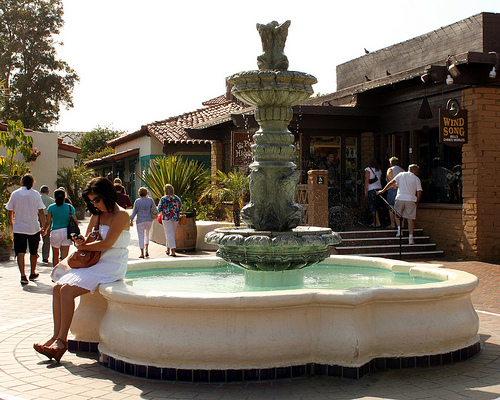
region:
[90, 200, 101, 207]
WOMAN IS WEARING SUN GLASSES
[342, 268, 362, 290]
WATER IN THE POND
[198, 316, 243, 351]
POND IS WHITE ON THE OUTSIDE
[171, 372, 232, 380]
LAYERS OF BRICKS AROUND THE BOTTOM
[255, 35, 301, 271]
WATER FOUNTAIN IN THE MIDDLE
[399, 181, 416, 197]
MAN IS WEARING A WHITE SHIRT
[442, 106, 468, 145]
SIGN ON THE SIDE OF WALL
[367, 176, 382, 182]
PURSE ON THE LADY ARM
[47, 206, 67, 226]
WOMAN WEARING A GREEN SHIRT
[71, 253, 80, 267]
LADY HOLDING PURSE IN ARMS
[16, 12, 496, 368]
A person is sitting on the water fountain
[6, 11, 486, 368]
People are walking around the area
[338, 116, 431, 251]
People are going into a building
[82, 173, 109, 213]
A person has dark colored hair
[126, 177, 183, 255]
Two people are walking somewhere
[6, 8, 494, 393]
The people are in a business area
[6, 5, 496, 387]
The people are out in the sunshine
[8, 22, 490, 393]
The people are on a vacation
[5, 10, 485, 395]
The people are enjoying their day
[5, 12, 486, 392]
The people are going to shop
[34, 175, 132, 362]
Woman sitting by fountain checking her cell phone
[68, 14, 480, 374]
Water fountain in the plaza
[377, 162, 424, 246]
Man wallking up steps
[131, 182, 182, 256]
Two women walking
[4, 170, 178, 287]
People waking in the stret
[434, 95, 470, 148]
Sign hanging from building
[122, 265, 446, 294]
Water in the fountain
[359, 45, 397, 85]
Three birds on the top of the building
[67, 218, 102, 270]
Brown purse in girl's arms.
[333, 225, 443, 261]
Steps to building entrance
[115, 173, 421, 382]
A fountain is white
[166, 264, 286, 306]
The water in the fountain is green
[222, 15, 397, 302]
The top of the fountain is green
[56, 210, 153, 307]
The girl is wearing a white dress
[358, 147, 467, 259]
The man is wearing a white shirt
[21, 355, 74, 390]
The ground is made of beige stone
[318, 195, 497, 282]
The stairs are by the restaurant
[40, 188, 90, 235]
The girl is wearing a green shirt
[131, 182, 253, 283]
The women are walking together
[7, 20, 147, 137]
A tree is in the distance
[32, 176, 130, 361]
woman sitting on a fountain at a resort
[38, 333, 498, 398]
dark shadow on the ground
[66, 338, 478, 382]
dark tiled bottom of the fountain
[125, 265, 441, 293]
bluish-green water in the fountain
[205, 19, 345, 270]
ornate statue in the middle of the fountain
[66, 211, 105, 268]
brown purse on the woman's shoulder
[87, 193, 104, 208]
dark sunglasses on the woman's tan face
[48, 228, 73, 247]
white shorts on the person with the turquoise shirt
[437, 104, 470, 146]
sign on the building with gold letters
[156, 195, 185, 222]
multi-colored print shirt on a woman with white pants